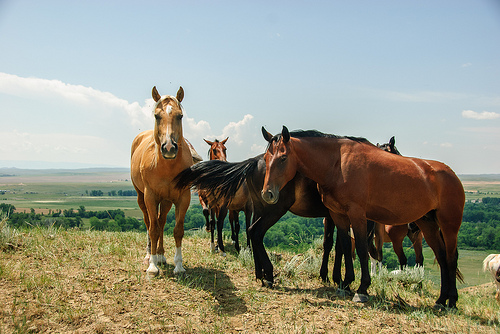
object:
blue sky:
[0, 0, 499, 174]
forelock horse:
[130, 85, 202, 276]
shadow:
[160, 262, 246, 317]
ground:
[0, 226, 500, 334]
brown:
[149, 165, 170, 186]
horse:
[258, 124, 464, 309]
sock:
[169, 251, 185, 274]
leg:
[173, 199, 193, 269]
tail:
[482, 253, 496, 271]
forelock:
[163, 104, 173, 114]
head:
[150, 85, 184, 161]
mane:
[288, 130, 370, 142]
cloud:
[458, 105, 498, 122]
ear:
[280, 125, 293, 142]